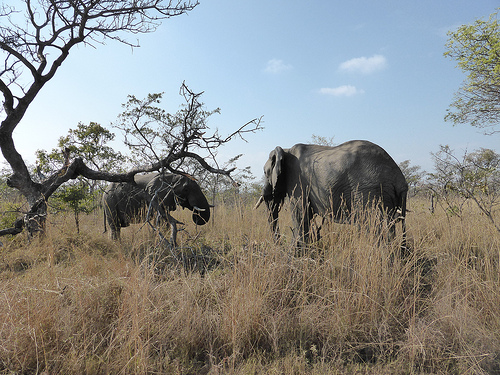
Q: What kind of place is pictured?
A: It is a field.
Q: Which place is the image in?
A: It is at the field.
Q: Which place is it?
A: It is a field.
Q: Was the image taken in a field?
A: Yes, it was taken in a field.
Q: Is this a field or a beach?
A: It is a field.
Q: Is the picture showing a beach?
A: No, the picture is showing a field.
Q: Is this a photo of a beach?
A: No, the picture is showing a field.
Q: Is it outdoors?
A: Yes, it is outdoors.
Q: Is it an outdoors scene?
A: Yes, it is outdoors.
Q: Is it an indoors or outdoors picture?
A: It is outdoors.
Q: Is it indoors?
A: No, it is outdoors.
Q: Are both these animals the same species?
A: Yes, all the animals are elephants.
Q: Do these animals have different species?
A: No, all the animals are elephants.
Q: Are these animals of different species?
A: No, all the animals are elephants.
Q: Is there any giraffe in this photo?
A: No, there are no giraffes.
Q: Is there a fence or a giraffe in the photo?
A: No, there are no giraffes or fences.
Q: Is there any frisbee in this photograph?
A: No, there are no frisbees.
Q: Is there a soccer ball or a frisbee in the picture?
A: No, there are no frisbees or soccer balls.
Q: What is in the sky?
A: The clouds are in the sky.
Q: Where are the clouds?
A: The clouds are in the sky.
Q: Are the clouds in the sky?
A: Yes, the clouds are in the sky.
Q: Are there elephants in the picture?
A: Yes, there is an elephant.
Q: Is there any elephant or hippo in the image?
A: Yes, there is an elephant.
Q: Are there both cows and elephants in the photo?
A: No, there is an elephant but no cows.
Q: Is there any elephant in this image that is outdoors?
A: Yes, there is an elephant that is outdoors.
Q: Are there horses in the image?
A: No, there are no horses.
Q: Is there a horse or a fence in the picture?
A: No, there are no horses or fences.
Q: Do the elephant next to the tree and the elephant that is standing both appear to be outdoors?
A: Yes, both the elephant and the elephant are outdoors.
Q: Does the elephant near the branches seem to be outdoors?
A: Yes, the elephant is outdoors.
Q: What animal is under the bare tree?
A: The elephant is under the tree.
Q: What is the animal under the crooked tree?
A: The animal is an elephant.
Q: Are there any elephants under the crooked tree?
A: Yes, there is an elephant under the tree.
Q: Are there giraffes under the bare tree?
A: No, there is an elephant under the tree.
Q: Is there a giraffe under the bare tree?
A: No, there is an elephant under the tree.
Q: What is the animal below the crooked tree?
A: The animal is an elephant.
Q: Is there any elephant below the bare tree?
A: Yes, there is an elephant below the tree.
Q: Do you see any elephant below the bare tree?
A: Yes, there is an elephant below the tree.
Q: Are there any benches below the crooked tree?
A: No, there is an elephant below the tree.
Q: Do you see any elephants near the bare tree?
A: Yes, there is an elephant near the tree.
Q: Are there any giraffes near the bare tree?
A: No, there is an elephant near the tree.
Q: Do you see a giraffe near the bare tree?
A: No, there is an elephant near the tree.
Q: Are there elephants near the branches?
A: Yes, there is an elephant near the branches.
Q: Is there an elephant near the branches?
A: Yes, there is an elephant near the branches.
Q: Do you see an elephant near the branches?
A: Yes, there is an elephant near the branches.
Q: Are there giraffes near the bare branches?
A: No, there is an elephant near the branches.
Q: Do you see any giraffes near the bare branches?
A: No, there is an elephant near the branches.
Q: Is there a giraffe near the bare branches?
A: No, there is an elephant near the branches.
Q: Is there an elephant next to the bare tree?
A: Yes, there is an elephant next to the tree.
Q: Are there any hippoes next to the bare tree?
A: No, there is an elephant next to the tree.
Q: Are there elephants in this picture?
A: Yes, there is an elephant.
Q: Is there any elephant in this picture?
A: Yes, there is an elephant.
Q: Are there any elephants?
A: Yes, there is an elephant.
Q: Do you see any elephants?
A: Yes, there is an elephant.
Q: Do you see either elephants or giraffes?
A: Yes, there is an elephant.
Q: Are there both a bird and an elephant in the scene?
A: No, there is an elephant but no birds.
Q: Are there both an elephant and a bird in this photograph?
A: No, there is an elephant but no birds.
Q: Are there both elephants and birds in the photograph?
A: No, there is an elephant but no birds.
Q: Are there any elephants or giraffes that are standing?
A: Yes, the elephant is standing.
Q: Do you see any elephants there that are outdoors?
A: Yes, there is an elephant that is outdoors.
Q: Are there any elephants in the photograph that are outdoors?
A: Yes, there is an elephant that is outdoors.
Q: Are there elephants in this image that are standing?
A: Yes, there is an elephant that is standing.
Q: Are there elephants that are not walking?
A: Yes, there is an elephant that is standing.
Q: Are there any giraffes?
A: No, there are no giraffes.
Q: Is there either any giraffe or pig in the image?
A: No, there are no giraffes or pigs.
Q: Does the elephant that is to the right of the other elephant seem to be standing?
A: Yes, the elephant is standing.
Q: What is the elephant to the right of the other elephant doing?
A: The elephant is standing.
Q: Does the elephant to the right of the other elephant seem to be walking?
A: No, the elephant is standing.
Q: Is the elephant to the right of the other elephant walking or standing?
A: The elephant is standing.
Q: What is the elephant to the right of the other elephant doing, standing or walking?
A: The elephant is standing.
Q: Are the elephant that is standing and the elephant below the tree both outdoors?
A: Yes, both the elephant and the elephant are outdoors.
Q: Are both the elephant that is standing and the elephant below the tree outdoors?
A: Yes, both the elephant and the elephant are outdoors.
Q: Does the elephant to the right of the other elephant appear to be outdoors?
A: Yes, the elephant is outdoors.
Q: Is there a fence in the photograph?
A: No, there are no fences.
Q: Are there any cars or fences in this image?
A: No, there are no fences or cars.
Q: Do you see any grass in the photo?
A: Yes, there is grass.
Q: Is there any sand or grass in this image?
A: Yes, there is grass.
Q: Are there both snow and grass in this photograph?
A: No, there is grass but no snow.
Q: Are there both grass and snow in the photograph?
A: No, there is grass but no snow.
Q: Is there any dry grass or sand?
A: Yes, there is dry grass.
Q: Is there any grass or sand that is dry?
A: Yes, the grass is dry.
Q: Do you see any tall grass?
A: Yes, there is tall grass.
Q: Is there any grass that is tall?
A: Yes, there is grass that is tall.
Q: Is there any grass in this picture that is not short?
A: Yes, there is tall grass.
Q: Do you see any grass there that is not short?
A: Yes, there is tall grass.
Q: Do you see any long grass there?
A: Yes, there is long grass.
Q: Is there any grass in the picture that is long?
A: Yes, there is grass that is long.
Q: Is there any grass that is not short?
A: Yes, there is long grass.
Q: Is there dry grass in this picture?
A: Yes, there is dry grass.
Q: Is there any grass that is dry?
A: Yes, there is dry grass.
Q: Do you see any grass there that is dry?
A: Yes, there is grass that is dry.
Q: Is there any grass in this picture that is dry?
A: Yes, there is grass that is dry.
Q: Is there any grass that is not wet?
A: Yes, there is dry grass.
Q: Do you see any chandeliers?
A: No, there are no chandeliers.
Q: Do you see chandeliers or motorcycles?
A: No, there are no chandeliers or motorcycles.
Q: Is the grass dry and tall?
A: Yes, the grass is dry and tall.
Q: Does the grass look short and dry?
A: No, the grass is dry but tall.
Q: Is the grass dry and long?
A: Yes, the grass is dry and long.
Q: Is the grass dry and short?
A: No, the grass is dry but long.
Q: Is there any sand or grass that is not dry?
A: No, there is grass but it is dry.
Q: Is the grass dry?
A: Yes, the grass is dry.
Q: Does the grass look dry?
A: Yes, the grass is dry.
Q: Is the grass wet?
A: No, the grass is dry.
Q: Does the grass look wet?
A: No, the grass is dry.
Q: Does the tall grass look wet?
A: No, the grass is dry.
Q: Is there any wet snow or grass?
A: No, there is grass but it is dry.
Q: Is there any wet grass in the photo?
A: No, there is grass but it is dry.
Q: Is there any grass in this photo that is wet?
A: No, there is grass but it is dry.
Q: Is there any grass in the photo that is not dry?
A: No, there is grass but it is dry.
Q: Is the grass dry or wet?
A: The grass is dry.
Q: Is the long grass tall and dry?
A: Yes, the grass is tall and dry.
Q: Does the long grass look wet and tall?
A: No, the grass is tall but dry.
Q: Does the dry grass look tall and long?
A: Yes, the grass is tall and long.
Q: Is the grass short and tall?
A: No, the grass is tall but long.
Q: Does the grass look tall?
A: Yes, the grass is tall.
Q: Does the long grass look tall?
A: Yes, the grass is tall.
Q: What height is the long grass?
A: The grass is tall.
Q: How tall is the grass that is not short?
A: The grass is tall.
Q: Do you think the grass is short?
A: No, the grass is tall.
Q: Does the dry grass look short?
A: No, the grass is tall.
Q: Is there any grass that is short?
A: No, there is grass but it is tall.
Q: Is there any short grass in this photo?
A: No, there is grass but it is tall.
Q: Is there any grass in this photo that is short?
A: No, there is grass but it is tall.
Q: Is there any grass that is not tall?
A: No, there is grass but it is tall.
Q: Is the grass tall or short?
A: The grass is tall.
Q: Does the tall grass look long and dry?
A: Yes, the grass is long and dry.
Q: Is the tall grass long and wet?
A: No, the grass is long but dry.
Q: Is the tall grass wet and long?
A: No, the grass is long but dry.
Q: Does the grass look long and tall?
A: Yes, the grass is long and tall.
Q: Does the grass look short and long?
A: No, the grass is long but tall.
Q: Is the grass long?
A: Yes, the grass is long.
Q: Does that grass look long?
A: Yes, the grass is long.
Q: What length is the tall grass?
A: The grass is long.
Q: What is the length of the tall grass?
A: The grass is long.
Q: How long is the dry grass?
A: The grass is long.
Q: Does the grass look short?
A: No, the grass is long.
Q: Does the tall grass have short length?
A: No, the grass is long.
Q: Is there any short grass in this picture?
A: No, there is grass but it is long.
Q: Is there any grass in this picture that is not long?
A: No, there is grass but it is long.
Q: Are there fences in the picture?
A: No, there are no fences.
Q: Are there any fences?
A: No, there are no fences.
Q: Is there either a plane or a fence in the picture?
A: No, there are no fences or airplanes.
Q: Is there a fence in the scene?
A: No, there are no fences.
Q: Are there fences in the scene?
A: No, there are no fences.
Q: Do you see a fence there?
A: No, there are no fences.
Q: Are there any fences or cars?
A: No, there are no fences or cars.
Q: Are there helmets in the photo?
A: No, there are no helmets.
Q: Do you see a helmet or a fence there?
A: No, there are no helmets or fences.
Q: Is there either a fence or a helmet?
A: No, there are no helmets or fences.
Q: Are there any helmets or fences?
A: No, there are no helmets or fences.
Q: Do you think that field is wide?
A: Yes, the field is wide.